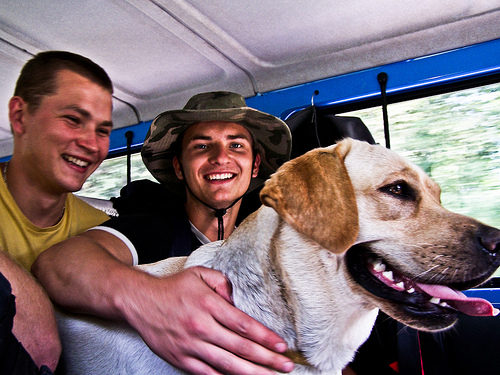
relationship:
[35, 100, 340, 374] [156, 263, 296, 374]
man has hand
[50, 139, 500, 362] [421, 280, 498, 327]
dog has tongue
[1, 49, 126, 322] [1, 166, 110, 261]
man wearing shirt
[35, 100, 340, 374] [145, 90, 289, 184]
man wearing hat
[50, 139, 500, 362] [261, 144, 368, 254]
dog has ear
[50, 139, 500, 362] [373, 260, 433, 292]
dog has teeth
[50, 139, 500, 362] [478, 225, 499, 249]
dog has nose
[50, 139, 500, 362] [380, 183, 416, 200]
dog has eye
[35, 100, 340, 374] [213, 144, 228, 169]
man has nose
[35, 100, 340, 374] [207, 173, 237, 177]
man has teeth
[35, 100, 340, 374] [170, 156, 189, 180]
man has ear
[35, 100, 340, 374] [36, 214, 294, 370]
man has arm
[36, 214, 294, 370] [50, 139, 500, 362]
arm around dog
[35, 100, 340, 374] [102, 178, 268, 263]
man wearing shirt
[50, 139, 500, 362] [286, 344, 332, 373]
dog wearing collar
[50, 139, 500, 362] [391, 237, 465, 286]
dog has whiskers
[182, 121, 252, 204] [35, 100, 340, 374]
face of man